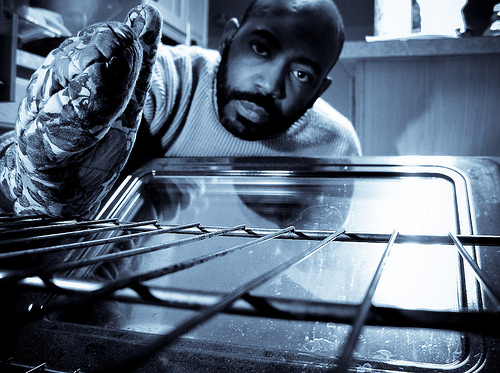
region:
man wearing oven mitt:
[1, 2, 165, 219]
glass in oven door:
[47, 170, 464, 362]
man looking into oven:
[1, 0, 366, 225]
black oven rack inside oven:
[0, 211, 496, 371]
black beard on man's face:
[211, 35, 304, 142]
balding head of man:
[248, 0, 349, 47]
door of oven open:
[34, 153, 496, 371]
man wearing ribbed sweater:
[143, 44, 362, 161]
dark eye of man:
[293, 67, 305, 78]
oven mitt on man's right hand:
[2, 1, 165, 219]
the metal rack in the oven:
[7, 215, 499, 364]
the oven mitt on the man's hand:
[1, 5, 158, 215]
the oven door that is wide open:
[62, 150, 489, 370]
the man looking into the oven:
[123, 2, 350, 176]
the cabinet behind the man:
[341, 42, 499, 156]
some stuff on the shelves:
[0, 4, 62, 112]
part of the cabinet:
[146, 5, 208, 45]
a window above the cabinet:
[380, 2, 456, 38]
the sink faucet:
[408, 8, 420, 36]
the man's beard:
[206, 48, 307, 143]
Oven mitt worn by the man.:
[17, 12, 155, 218]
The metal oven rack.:
[10, 210, 497, 365]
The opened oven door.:
[17, 157, 498, 363]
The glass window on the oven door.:
[50, 177, 462, 354]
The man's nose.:
[252, 67, 284, 101]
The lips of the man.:
[231, 92, 273, 129]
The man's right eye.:
[290, 62, 311, 90]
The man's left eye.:
[250, 44, 270, 64]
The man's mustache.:
[234, 85, 288, 115]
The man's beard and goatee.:
[211, 47, 324, 142]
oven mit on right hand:
[5, 7, 161, 222]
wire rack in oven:
[10, 210, 493, 356]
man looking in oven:
[103, 1, 370, 156]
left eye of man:
[290, 65, 310, 82]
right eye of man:
[250, 41, 266, 58]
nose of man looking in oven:
[251, 58, 291, 96]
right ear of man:
[218, 16, 242, 52]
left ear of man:
[313, 76, 333, 107]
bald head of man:
[246, 0, 348, 57]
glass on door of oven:
[46, 165, 467, 357]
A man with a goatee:
[194, 2, 359, 145]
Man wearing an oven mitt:
[4, 10, 334, 216]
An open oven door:
[67, 148, 497, 371]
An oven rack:
[11, 217, 416, 356]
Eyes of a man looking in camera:
[241, 31, 315, 88]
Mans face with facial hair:
[208, 31, 324, 142]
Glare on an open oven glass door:
[339, 140, 491, 366]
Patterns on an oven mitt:
[36, 56, 135, 176]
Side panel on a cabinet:
[382, 68, 492, 148]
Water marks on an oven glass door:
[284, 321, 414, 372]